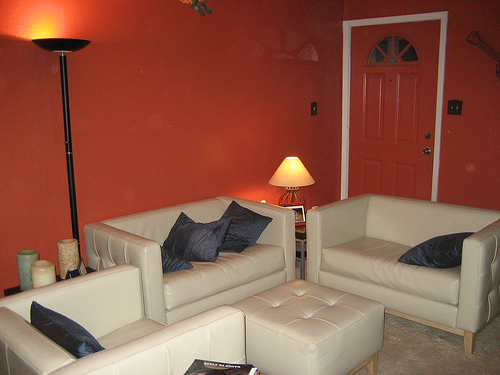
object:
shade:
[264, 154, 318, 194]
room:
[9, 3, 497, 373]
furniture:
[0, 192, 498, 372]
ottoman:
[221, 266, 383, 371]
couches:
[2, 246, 257, 372]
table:
[3, 265, 93, 301]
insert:
[358, 31, 423, 67]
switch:
[444, 95, 468, 115]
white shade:
[269, 151, 319, 189]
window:
[365, 33, 421, 68]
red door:
[345, 14, 442, 201]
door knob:
[419, 145, 433, 156]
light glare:
[0, 0, 68, 37]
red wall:
[0, 0, 499, 218]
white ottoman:
[227, 276, 386, 373]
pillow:
[398, 228, 474, 268]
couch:
[305, 192, 485, 309]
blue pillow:
[398, 227, 468, 267]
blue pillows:
[217, 199, 272, 242]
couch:
[82, 194, 298, 310]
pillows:
[131, 180, 301, 289]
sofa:
[64, 177, 301, 289]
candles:
[15, 234, 97, 286]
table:
[42, 215, 179, 361]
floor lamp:
[33, 36, 92, 273]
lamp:
[266, 155, 316, 207]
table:
[293, 216, 308, 274]